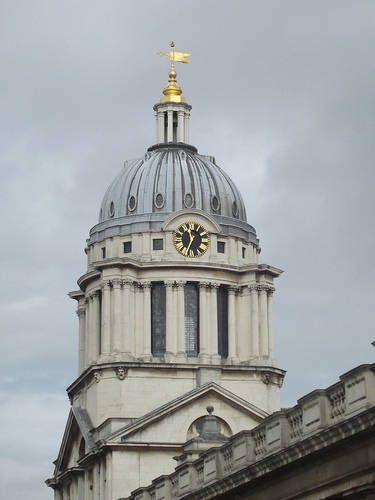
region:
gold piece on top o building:
[153, 33, 206, 102]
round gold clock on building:
[163, 215, 220, 265]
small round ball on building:
[202, 403, 217, 416]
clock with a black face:
[168, 221, 224, 257]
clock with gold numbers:
[170, 219, 210, 262]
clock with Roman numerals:
[168, 218, 214, 263]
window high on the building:
[182, 278, 200, 365]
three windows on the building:
[140, 280, 240, 364]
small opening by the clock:
[151, 234, 165, 251]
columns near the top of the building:
[77, 268, 142, 373]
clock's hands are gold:
[172, 220, 208, 254]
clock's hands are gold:
[173, 208, 212, 274]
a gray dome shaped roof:
[105, 145, 212, 206]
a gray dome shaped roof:
[108, 172, 204, 221]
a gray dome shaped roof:
[184, 141, 254, 220]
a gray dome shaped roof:
[140, 124, 228, 219]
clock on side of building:
[155, 209, 218, 260]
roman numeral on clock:
[187, 249, 199, 257]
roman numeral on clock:
[186, 221, 195, 233]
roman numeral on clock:
[168, 235, 183, 241]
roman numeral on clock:
[197, 236, 210, 242]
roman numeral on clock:
[196, 243, 208, 253]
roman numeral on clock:
[195, 224, 202, 232]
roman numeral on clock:
[171, 236, 181, 242]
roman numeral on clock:
[180, 225, 187, 230]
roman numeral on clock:
[172, 241, 182, 251]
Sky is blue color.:
[244, 44, 336, 155]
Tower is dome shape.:
[92, 139, 290, 260]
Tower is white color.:
[99, 179, 270, 423]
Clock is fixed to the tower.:
[163, 219, 231, 272]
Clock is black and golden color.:
[165, 220, 225, 260]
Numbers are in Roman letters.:
[172, 213, 217, 267]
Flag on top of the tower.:
[157, 41, 192, 92]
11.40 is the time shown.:
[165, 220, 212, 268]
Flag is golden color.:
[158, 36, 194, 96]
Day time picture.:
[56, 134, 345, 413]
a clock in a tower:
[170, 218, 213, 263]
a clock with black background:
[167, 216, 213, 264]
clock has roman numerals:
[170, 219, 213, 259]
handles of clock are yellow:
[168, 216, 214, 263]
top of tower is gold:
[143, 28, 194, 109]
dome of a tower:
[76, 141, 262, 259]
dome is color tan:
[82, 140, 263, 263]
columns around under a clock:
[58, 264, 281, 371]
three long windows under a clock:
[143, 276, 235, 367]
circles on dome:
[87, 185, 254, 221]